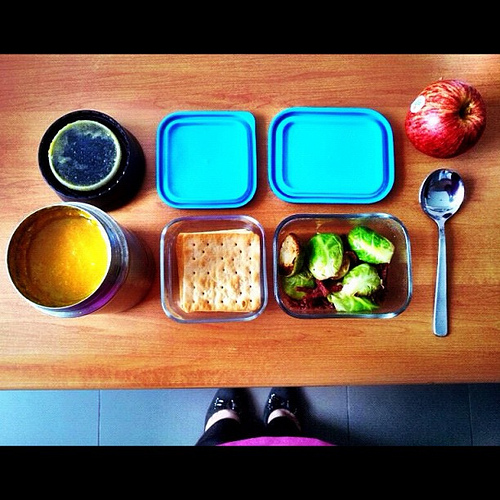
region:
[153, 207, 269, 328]
a bowl of crackers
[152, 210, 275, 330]
the crackers are brown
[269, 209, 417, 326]
a bowl with green vegetables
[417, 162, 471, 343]
a spook next a bowl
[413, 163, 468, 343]
a silver spoon on table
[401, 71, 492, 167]
a red apple on table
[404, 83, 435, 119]
a sticker on apple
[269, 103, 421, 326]
a lid above a bowl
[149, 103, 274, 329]
a lid above the bowl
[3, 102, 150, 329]
a lid of jar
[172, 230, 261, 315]
flat bread in container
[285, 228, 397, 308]
a leafy salad in container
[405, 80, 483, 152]
a red apple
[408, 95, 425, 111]
white sticker on an apple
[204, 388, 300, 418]
pair of black shoes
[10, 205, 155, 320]
an open thermos with yellow soup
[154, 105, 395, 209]
blue plastic lids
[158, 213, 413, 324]
two glass containers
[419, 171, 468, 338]
a shiny metal spoon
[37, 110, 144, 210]
a black lid to thermos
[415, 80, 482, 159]
Red apple on the wooden table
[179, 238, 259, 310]
White and brown cracker in glass container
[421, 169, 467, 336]
Silver spoon on wooden table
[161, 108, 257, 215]
Blue lid that covers the crackers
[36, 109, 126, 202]
Black lid for thermos cup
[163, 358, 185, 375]
Small part of wooden table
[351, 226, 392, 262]
One piece of lettuce in glass container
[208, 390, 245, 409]
Left black shoe of the person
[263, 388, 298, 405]
Right black shoe of the female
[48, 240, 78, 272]
Soup like substance in thermos cup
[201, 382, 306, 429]
A pair of black shoes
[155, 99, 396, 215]
Two blue container lids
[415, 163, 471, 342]
Spoon made of silver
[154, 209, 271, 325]
Crackers in a container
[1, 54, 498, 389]
A brown wooden table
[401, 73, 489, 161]
A round red apple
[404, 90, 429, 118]
Sticker on an apple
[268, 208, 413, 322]
Vegetables in a bowl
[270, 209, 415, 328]
A rectangle shaped bowl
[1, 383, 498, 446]
Tiles on the floor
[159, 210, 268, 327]
A square glass food container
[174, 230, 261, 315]
Crackers in the food container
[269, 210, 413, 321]
A rectangular glass food container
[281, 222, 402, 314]
Vegetables in a food container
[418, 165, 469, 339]
A shiny silver spoon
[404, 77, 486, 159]
A mottled red apple on the table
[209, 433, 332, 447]
Part of a pink shirt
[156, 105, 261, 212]
A square blue food container lid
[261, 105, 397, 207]
A rectangular blue food container lid